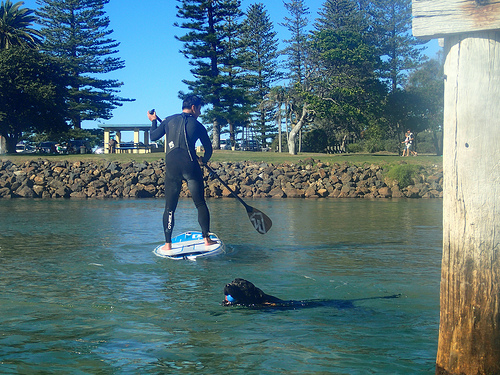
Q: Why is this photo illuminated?
A: Sunlight.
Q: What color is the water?
A: Blue.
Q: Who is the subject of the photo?
A: The paddleboarder.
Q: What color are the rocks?
A: Gray.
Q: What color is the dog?
A: Black.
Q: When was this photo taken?
A: During the day.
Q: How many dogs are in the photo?
A: One.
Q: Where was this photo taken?
A: In a park.